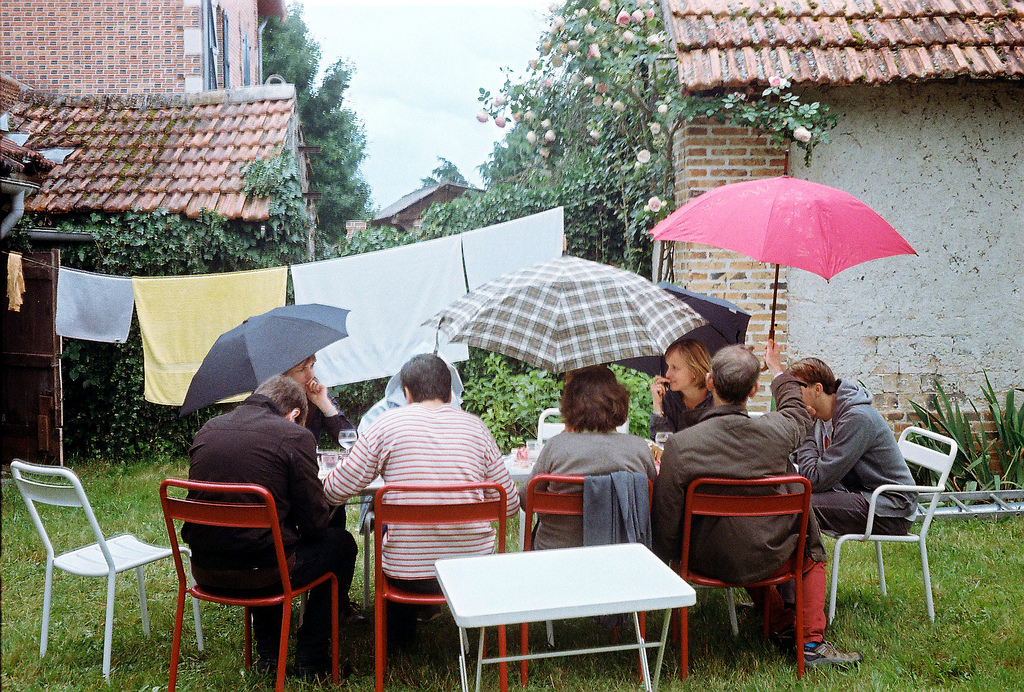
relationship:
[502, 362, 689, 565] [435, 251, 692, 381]
lady has umbrella